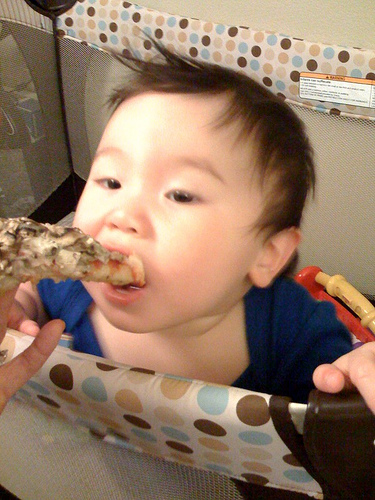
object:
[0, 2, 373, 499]
playpin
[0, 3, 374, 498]
baby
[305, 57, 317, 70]
dot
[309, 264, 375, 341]
toy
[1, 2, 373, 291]
background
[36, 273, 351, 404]
shirt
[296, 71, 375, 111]
warning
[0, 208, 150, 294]
pizza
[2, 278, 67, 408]
person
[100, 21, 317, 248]
hair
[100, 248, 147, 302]
mouth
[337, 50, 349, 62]
spot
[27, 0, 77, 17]
corner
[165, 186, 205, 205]
eye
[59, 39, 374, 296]
net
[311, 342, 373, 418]
hand